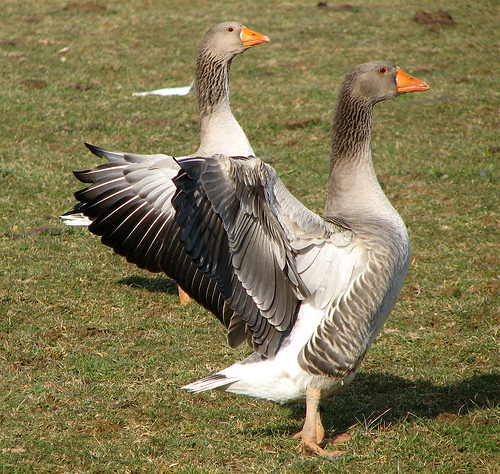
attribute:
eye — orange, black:
[375, 67, 395, 83]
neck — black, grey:
[198, 51, 227, 114]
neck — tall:
[333, 78, 371, 183]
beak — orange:
[393, 63, 430, 93]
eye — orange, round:
[375, 63, 388, 78]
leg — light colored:
[295, 380, 335, 453]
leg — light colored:
[293, 407, 327, 448]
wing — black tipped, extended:
[75, 143, 182, 283]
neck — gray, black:
[326, 89, 376, 199]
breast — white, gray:
[366, 186, 411, 337]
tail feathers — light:
[180, 361, 239, 397]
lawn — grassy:
[0, 4, 499, 469]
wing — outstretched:
[198, 153, 307, 337]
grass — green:
[2, 0, 497, 470]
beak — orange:
[236, 23, 270, 52]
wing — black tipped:
[195, 154, 315, 334]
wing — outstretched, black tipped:
[161, 156, 288, 357]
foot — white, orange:
[290, 434, 343, 460]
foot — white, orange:
[291, 417, 325, 444]